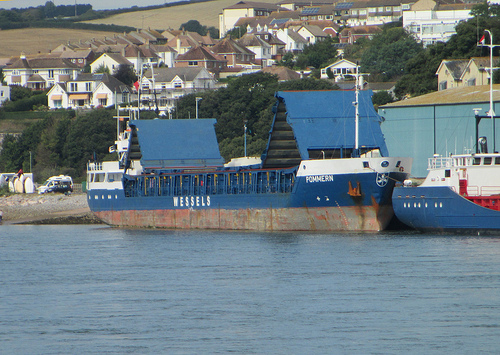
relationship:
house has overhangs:
[177, 40, 219, 73] [41, 65, 99, 92]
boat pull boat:
[84, 156, 411, 232] [388, 149, 498, 238]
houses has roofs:
[29, 21, 244, 136] [1, 27, 213, 56]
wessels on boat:
[170, 195, 212, 207] [91, 156, 400, 229]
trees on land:
[22, 18, 424, 150] [2, 11, 491, 181]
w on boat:
[168, 194, 193, 210] [77, 158, 402, 247]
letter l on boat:
[198, 195, 206, 206] [77, 158, 402, 247]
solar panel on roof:
[297, 2, 315, 16] [296, 4, 350, 19]